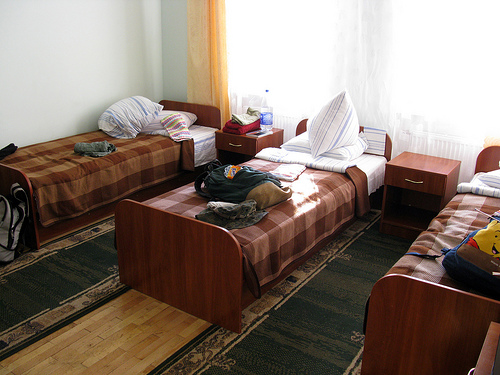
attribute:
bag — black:
[196, 161, 299, 216]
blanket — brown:
[23, 136, 201, 194]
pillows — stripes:
[285, 104, 375, 182]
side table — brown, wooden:
[214, 128, 256, 171]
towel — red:
[226, 120, 260, 135]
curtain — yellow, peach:
[180, 4, 230, 135]